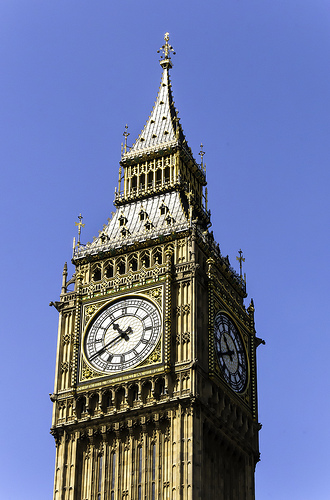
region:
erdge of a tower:
[182, 441, 196, 463]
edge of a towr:
[184, 436, 197, 455]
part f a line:
[154, 448, 172, 485]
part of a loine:
[193, 436, 203, 455]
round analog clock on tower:
[77, 298, 164, 364]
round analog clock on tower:
[210, 303, 259, 402]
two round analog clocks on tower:
[64, 288, 262, 413]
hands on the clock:
[88, 305, 151, 353]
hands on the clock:
[217, 323, 239, 373]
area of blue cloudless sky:
[279, 425, 310, 472]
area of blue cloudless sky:
[276, 248, 296, 306]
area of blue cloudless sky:
[6, 343, 45, 398]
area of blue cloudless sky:
[12, 221, 46, 280]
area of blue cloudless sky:
[15, 116, 70, 159]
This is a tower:
[37, 26, 286, 498]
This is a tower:
[64, 203, 103, 273]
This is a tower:
[231, 238, 253, 293]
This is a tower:
[247, 292, 262, 401]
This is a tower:
[46, 246, 85, 362]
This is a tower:
[162, 230, 188, 383]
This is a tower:
[137, 16, 213, 201]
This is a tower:
[108, 112, 167, 235]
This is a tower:
[163, 95, 200, 204]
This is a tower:
[85, 21, 250, 381]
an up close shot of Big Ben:
[44, 25, 266, 499]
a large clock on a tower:
[75, 272, 168, 387]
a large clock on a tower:
[199, 296, 260, 401]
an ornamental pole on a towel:
[72, 208, 83, 241]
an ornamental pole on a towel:
[233, 246, 246, 278]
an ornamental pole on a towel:
[182, 182, 198, 209]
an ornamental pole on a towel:
[119, 122, 132, 148]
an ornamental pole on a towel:
[197, 141, 205, 171]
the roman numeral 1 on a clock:
[130, 305, 140, 316]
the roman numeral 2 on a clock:
[140, 312, 150, 320]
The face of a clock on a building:
[82, 291, 163, 373]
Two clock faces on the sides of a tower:
[82, 295, 250, 394]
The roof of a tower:
[70, 27, 268, 286]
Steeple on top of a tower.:
[157, 27, 175, 64]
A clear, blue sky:
[1, 1, 329, 144]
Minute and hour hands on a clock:
[89, 322, 131, 360]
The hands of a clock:
[217, 332, 236, 360]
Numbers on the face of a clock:
[107, 306, 153, 321]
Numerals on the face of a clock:
[218, 362, 246, 390]